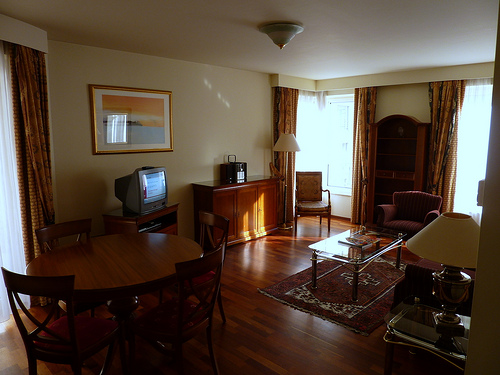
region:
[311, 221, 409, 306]
Glass top coffee table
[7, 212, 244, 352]
Wooden table with four chairs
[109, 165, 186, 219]
TV sitting on a stand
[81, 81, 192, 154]
Painting hangs on the wall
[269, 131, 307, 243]
Standing lamp with white shade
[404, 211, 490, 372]
Table lamp with beige shade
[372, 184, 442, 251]
Red fluffy chair by table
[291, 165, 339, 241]
Arm chair in corner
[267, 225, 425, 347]
Red rug under table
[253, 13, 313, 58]
Light fixture in ceiling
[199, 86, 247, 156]
this is the wall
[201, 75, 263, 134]
the wall is white in color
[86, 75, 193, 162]
this is a picture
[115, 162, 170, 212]
this is a television set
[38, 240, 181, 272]
this is a table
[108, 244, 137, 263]
the table is brown in color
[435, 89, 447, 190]
this is a curtain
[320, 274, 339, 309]
this is a carpet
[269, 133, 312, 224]
this is a lampshade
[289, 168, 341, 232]
this is a chair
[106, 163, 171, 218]
A grey T.V.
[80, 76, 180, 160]
A picture on the wall.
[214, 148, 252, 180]
radio on the stand.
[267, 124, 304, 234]
A standing lamp.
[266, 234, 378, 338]
A rug under the table.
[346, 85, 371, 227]
A curtain by the window.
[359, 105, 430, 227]
A large book shelf.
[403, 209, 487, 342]
A lamp on the end table.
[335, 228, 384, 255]
Magazines on the coffee table.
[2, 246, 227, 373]
Chairs at the table.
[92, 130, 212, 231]
the television is open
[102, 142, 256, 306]
the television is open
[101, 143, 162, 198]
the television is open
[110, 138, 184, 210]
the television is open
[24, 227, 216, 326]
The table in the room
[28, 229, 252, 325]
The table is wooden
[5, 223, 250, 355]
the table has four chairs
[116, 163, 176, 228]
the television on the tv stand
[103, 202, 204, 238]
The tv stand is made of wood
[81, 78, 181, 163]
The painting hanging on the wall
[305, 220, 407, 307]
The glass coffee table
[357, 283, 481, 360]
The glass end table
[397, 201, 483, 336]
The lamp on the end table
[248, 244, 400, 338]
The burgundy rug under the coffee table